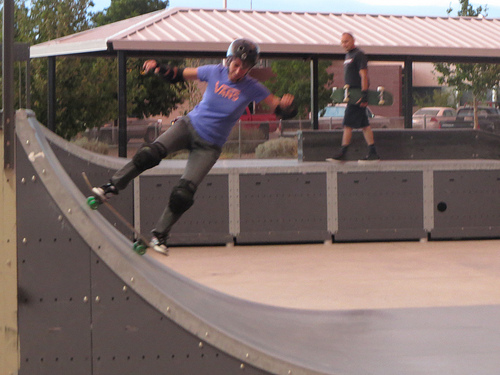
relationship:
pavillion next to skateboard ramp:
[36, 18, 482, 180] [14, 107, 498, 370]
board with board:
[74, 163, 187, 264] [74, 163, 187, 264]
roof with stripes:
[29, 7, 486, 59] [280, 16, 312, 46]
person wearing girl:
[98, 14, 288, 258] [153, 25, 278, 286]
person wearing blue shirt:
[98, 14, 288, 258] [187, 62, 269, 145]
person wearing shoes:
[98, 14, 288, 258] [93, 178, 189, 268]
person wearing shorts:
[317, 25, 395, 162] [328, 90, 385, 140]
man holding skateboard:
[326, 31, 390, 160] [330, 84, 394, 109]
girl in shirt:
[153, 25, 278, 286] [194, 56, 249, 161]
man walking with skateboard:
[326, 31, 390, 160] [330, 84, 394, 109]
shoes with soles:
[93, 178, 189, 268] [150, 242, 167, 255]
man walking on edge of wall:
[330, 31, 382, 161] [45, 141, 485, 238]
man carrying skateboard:
[326, 31, 390, 160] [330, 84, 394, 109]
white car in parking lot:
[406, 103, 456, 132] [94, 100, 475, 145]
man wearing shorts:
[326, 31, 390, 160] [340, 100, 370, 127]